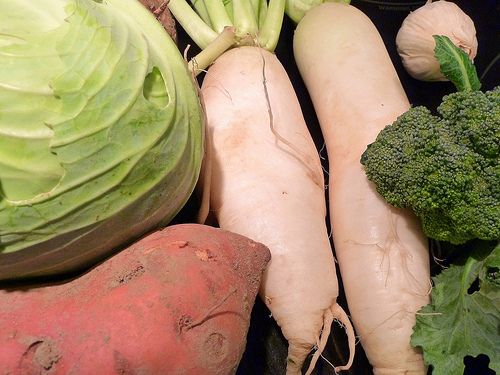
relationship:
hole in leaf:
[143, 66, 170, 109] [1, 1, 207, 279]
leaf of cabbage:
[1, 1, 207, 279] [0, 1, 206, 279]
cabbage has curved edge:
[0, 1, 206, 279] [0, 0, 79, 213]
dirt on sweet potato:
[36, 341, 60, 370] [1, 222, 270, 374]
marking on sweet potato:
[204, 333, 228, 361] [1, 222, 270, 374]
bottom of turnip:
[259, 256, 356, 375] [201, 48, 357, 374]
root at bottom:
[287, 341, 315, 374] [259, 256, 356, 375]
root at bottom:
[304, 308, 334, 374] [259, 256, 356, 375]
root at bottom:
[332, 303, 357, 373] [259, 256, 356, 375]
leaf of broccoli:
[434, 35, 480, 92] [361, 85, 499, 241]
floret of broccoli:
[438, 86, 499, 154] [361, 85, 499, 241]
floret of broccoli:
[362, 106, 472, 213] [361, 85, 499, 241]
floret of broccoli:
[409, 143, 498, 245] [361, 85, 499, 241]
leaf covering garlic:
[1, 1, 207, 279] [395, 1, 477, 85]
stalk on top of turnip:
[166, 1, 217, 46] [201, 48, 357, 374]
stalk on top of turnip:
[205, 1, 232, 34] [201, 48, 357, 374]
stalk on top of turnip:
[233, 1, 258, 38] [201, 48, 357, 374]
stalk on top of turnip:
[258, 0, 287, 52] [201, 48, 357, 374]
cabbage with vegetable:
[0, 1, 206, 279] [142, 1, 178, 43]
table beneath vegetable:
[0, 2, 499, 375] [142, 1, 178, 43]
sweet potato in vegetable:
[1, 222, 270, 374] [142, 1, 178, 43]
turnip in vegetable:
[201, 48, 357, 374] [142, 1, 178, 43]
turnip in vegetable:
[292, 3, 434, 374] [142, 1, 178, 43]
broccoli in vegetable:
[361, 85, 499, 241] [142, 1, 178, 43]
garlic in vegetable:
[395, 1, 477, 85] [142, 1, 178, 43]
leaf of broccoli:
[411, 244, 499, 373] [361, 85, 499, 241]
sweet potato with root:
[1, 222, 270, 374] [185, 45, 213, 224]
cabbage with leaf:
[0, 1, 206, 279] [1, 1, 207, 279]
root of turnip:
[287, 341, 315, 374] [201, 48, 357, 374]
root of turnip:
[304, 308, 334, 374] [201, 48, 357, 374]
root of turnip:
[332, 303, 357, 373] [201, 48, 357, 374]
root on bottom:
[287, 341, 315, 374] [259, 256, 356, 375]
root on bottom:
[304, 308, 334, 374] [259, 256, 356, 375]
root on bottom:
[332, 303, 357, 373] [259, 256, 356, 375]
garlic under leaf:
[395, 1, 477, 85] [434, 35, 480, 92]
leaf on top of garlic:
[434, 35, 480, 92] [395, 1, 477, 85]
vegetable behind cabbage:
[142, 1, 178, 43] [0, 1, 206, 279]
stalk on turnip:
[166, 1, 217, 46] [201, 48, 357, 374]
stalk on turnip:
[205, 1, 232, 34] [201, 48, 357, 374]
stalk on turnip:
[233, 1, 258, 38] [201, 48, 357, 374]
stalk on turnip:
[258, 0, 287, 52] [201, 48, 357, 374]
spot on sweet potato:
[117, 264, 145, 286] [1, 222, 270, 374]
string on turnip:
[259, 46, 313, 162] [201, 48, 357, 374]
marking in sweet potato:
[204, 333, 228, 361] [1, 222, 270, 374]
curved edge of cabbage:
[0, 0, 79, 213] [0, 1, 206, 279]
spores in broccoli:
[361, 85, 499, 247] [361, 85, 499, 241]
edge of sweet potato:
[179, 222, 270, 373] [1, 222, 270, 374]